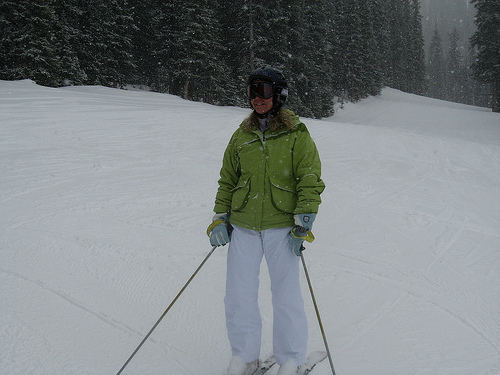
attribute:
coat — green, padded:
[208, 111, 327, 215]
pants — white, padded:
[231, 218, 308, 358]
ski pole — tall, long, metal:
[297, 253, 364, 374]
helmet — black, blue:
[245, 58, 295, 91]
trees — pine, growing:
[149, 4, 236, 85]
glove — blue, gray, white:
[204, 218, 236, 244]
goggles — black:
[239, 78, 277, 99]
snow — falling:
[426, 8, 470, 43]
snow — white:
[343, 161, 455, 327]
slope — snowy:
[395, 90, 485, 204]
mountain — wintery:
[225, 29, 491, 342]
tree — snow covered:
[171, 11, 220, 76]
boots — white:
[225, 356, 264, 374]